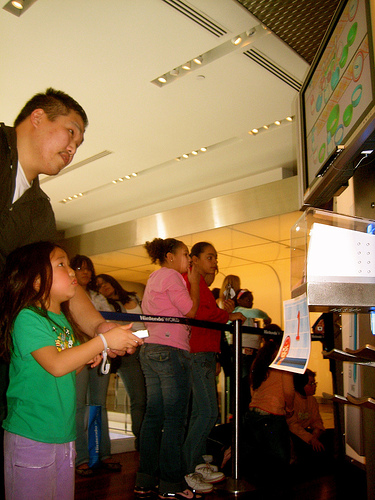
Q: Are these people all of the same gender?
A: Yes, all the people are female.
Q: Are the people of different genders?
A: No, all the people are female.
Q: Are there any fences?
A: No, there are no fences.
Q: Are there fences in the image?
A: No, there are no fences.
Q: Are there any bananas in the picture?
A: Yes, there is a banana.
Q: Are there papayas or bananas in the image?
A: Yes, there is a banana.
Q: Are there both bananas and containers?
A: No, there is a banana but no containers.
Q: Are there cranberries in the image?
A: No, there are no cranberries.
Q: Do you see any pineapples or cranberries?
A: No, there are no cranberries or pineapples.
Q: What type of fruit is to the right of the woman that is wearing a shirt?
A: The fruit is a banana.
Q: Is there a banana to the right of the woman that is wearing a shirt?
A: Yes, there is a banana to the right of the woman.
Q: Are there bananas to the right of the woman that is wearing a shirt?
A: Yes, there is a banana to the right of the woman.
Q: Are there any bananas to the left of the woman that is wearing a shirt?
A: No, the banana is to the right of the woman.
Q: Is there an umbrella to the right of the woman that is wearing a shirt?
A: No, there is a banana to the right of the woman.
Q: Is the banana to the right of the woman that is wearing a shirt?
A: Yes, the banana is to the right of the woman.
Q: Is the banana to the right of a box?
A: No, the banana is to the right of the woman.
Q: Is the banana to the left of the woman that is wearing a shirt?
A: No, the banana is to the right of the woman.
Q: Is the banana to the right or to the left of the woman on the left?
A: The banana is to the right of the woman.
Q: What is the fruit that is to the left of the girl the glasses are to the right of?
A: The fruit is a banana.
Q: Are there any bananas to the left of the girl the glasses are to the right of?
A: Yes, there is a banana to the left of the girl.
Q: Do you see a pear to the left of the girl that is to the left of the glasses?
A: No, there is a banana to the left of the girl.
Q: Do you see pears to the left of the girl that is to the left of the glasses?
A: No, there is a banana to the left of the girl.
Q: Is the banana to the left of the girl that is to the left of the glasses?
A: Yes, the banana is to the left of the girl.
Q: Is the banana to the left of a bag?
A: No, the banana is to the left of the girl.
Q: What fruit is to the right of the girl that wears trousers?
A: The fruit is a banana.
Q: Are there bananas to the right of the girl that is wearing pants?
A: Yes, there is a banana to the right of the girl.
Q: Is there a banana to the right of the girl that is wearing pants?
A: Yes, there is a banana to the right of the girl.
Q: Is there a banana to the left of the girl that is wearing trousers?
A: No, the banana is to the right of the girl.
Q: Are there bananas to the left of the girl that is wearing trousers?
A: No, the banana is to the right of the girl.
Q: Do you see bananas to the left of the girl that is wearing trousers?
A: No, the banana is to the right of the girl.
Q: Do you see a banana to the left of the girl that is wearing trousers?
A: No, the banana is to the right of the girl.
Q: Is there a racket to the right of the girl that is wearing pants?
A: No, there is a banana to the right of the girl.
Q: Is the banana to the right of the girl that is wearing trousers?
A: Yes, the banana is to the right of the girl.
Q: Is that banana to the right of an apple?
A: No, the banana is to the right of the girl.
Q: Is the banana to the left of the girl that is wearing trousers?
A: No, the banana is to the right of the girl.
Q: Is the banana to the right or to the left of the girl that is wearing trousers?
A: The banana is to the right of the girl.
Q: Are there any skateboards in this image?
A: No, there are no skateboards.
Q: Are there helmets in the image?
A: No, there are no helmets.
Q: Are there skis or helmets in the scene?
A: No, there are no helmets or skis.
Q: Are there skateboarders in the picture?
A: No, there are no skateboarders.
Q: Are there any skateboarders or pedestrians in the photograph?
A: No, there are no skateboarders or pedestrians.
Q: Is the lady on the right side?
A: Yes, the lady is on the right of the image.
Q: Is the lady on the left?
A: No, the lady is on the right of the image.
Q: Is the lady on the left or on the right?
A: The lady is on the right of the image.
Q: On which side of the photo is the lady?
A: The lady is on the right of the image.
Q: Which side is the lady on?
A: The lady is on the right of the image.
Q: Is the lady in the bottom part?
A: Yes, the lady is in the bottom of the image.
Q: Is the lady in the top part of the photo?
A: No, the lady is in the bottom of the image.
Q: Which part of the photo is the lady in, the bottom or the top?
A: The lady is in the bottom of the image.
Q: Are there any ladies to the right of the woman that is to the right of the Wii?
A: Yes, there is a lady to the right of the woman.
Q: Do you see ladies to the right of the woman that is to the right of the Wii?
A: Yes, there is a lady to the right of the woman.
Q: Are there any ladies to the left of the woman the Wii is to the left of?
A: No, the lady is to the right of the woman.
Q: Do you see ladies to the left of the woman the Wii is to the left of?
A: No, the lady is to the right of the woman.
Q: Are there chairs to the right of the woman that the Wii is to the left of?
A: No, there is a lady to the right of the woman.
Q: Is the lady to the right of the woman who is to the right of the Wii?
A: Yes, the lady is to the right of the woman.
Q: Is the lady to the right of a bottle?
A: No, the lady is to the right of the woman.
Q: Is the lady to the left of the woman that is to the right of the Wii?
A: No, the lady is to the right of the woman.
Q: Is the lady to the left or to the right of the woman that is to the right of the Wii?
A: The lady is to the right of the woman.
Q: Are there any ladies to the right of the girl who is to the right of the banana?
A: Yes, there is a lady to the right of the girl.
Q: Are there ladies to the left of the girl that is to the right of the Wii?
A: No, the lady is to the right of the girl.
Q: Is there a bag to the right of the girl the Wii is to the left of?
A: No, there is a lady to the right of the girl.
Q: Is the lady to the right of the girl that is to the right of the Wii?
A: Yes, the lady is to the right of the girl.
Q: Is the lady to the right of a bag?
A: No, the lady is to the right of the girl.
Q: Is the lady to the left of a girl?
A: No, the lady is to the right of a girl.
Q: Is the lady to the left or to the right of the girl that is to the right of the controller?
A: The lady is to the right of the girl.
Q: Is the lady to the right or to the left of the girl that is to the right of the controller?
A: The lady is to the right of the girl.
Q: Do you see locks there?
A: No, there are no locks.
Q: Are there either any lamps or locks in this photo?
A: No, there are no locks or lamps.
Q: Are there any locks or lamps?
A: No, there are no locks or lamps.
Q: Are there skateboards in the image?
A: No, there are no skateboards.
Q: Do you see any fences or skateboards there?
A: No, there are no skateboards or fences.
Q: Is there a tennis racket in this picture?
A: No, there are no rackets.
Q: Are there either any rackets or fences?
A: No, there are no rackets or fences.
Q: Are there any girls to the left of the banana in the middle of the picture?
A: Yes, there is a girl to the left of the banana.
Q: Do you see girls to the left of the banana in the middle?
A: Yes, there is a girl to the left of the banana.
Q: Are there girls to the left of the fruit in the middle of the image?
A: Yes, there is a girl to the left of the banana.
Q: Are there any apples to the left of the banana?
A: No, there is a girl to the left of the banana.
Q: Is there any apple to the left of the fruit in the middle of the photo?
A: No, there is a girl to the left of the banana.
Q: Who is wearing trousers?
A: The girl is wearing trousers.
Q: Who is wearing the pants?
A: The girl is wearing trousers.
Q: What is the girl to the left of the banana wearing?
A: The girl is wearing trousers.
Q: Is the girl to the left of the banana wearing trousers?
A: Yes, the girl is wearing trousers.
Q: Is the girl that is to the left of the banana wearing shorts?
A: No, the girl is wearing trousers.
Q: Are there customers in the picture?
A: No, there are no customers.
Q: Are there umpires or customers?
A: No, there are no customers or umpires.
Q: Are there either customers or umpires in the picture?
A: No, there are no customers or umpires.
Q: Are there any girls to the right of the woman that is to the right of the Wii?
A: Yes, there is a girl to the right of the woman.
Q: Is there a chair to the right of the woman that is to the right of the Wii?
A: No, there is a girl to the right of the woman.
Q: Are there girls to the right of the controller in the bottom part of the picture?
A: Yes, there is a girl to the right of the controller.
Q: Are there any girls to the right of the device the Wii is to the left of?
A: Yes, there is a girl to the right of the controller.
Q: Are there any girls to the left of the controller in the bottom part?
A: No, the girl is to the right of the controller.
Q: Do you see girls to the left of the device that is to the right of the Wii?
A: No, the girl is to the right of the controller.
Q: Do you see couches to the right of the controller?
A: No, there is a girl to the right of the controller.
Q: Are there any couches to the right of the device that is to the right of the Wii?
A: No, there is a girl to the right of the controller.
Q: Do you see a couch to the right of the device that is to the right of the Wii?
A: No, there is a girl to the right of the controller.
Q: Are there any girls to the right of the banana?
A: Yes, there is a girl to the right of the banana.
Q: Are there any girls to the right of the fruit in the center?
A: Yes, there is a girl to the right of the banana.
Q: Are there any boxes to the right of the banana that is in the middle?
A: No, there is a girl to the right of the banana.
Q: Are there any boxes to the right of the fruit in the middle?
A: No, there is a girl to the right of the banana.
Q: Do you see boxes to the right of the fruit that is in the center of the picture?
A: No, there is a girl to the right of the banana.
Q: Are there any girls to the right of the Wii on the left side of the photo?
A: Yes, there is a girl to the right of the Wii.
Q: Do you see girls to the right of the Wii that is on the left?
A: Yes, there is a girl to the right of the Wii.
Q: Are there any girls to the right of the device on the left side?
A: Yes, there is a girl to the right of the Wii.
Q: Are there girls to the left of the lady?
A: Yes, there is a girl to the left of the lady.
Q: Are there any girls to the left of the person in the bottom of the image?
A: Yes, there is a girl to the left of the lady.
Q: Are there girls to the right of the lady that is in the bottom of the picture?
A: No, the girl is to the left of the lady.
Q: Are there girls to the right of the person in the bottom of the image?
A: No, the girl is to the left of the lady.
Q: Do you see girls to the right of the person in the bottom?
A: No, the girl is to the left of the lady.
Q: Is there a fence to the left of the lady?
A: No, there is a girl to the left of the lady.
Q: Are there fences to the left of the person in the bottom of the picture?
A: No, there is a girl to the left of the lady.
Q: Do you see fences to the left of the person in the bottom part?
A: No, there is a girl to the left of the lady.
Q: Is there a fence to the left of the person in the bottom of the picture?
A: No, there is a girl to the left of the lady.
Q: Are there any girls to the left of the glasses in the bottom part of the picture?
A: Yes, there is a girl to the left of the glasses.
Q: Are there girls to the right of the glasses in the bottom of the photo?
A: No, the girl is to the left of the glasses.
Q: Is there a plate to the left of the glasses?
A: No, there is a girl to the left of the glasses.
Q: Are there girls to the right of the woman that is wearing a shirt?
A: Yes, there is a girl to the right of the woman.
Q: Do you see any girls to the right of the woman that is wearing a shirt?
A: Yes, there is a girl to the right of the woman.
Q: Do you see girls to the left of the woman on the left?
A: No, the girl is to the right of the woman.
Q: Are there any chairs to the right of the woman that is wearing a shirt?
A: No, there is a girl to the right of the woman.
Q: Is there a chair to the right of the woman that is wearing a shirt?
A: No, there is a girl to the right of the woman.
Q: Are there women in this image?
A: Yes, there is a woman.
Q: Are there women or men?
A: Yes, there is a woman.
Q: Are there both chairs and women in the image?
A: No, there is a woman but no chairs.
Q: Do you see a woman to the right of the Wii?
A: Yes, there is a woman to the right of the Wii.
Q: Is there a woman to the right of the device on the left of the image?
A: Yes, there is a woman to the right of the Wii.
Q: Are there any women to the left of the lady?
A: Yes, there is a woman to the left of the lady.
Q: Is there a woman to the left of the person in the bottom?
A: Yes, there is a woman to the left of the lady.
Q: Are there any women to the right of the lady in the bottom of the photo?
A: No, the woman is to the left of the lady.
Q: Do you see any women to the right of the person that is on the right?
A: No, the woman is to the left of the lady.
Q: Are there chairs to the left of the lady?
A: No, there is a woman to the left of the lady.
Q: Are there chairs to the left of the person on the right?
A: No, there is a woman to the left of the lady.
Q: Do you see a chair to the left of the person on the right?
A: No, there is a woman to the left of the lady.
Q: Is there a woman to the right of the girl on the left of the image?
A: Yes, there is a woman to the right of the girl.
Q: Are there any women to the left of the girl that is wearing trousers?
A: No, the woman is to the right of the girl.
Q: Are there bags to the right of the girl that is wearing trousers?
A: No, there is a woman to the right of the girl.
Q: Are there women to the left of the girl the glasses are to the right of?
A: Yes, there is a woman to the left of the girl.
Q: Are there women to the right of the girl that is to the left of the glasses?
A: No, the woman is to the left of the girl.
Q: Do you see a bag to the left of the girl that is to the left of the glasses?
A: No, there is a woman to the left of the girl.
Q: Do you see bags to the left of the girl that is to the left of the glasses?
A: No, there is a woman to the left of the girl.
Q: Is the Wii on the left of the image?
A: Yes, the Wii is on the left of the image.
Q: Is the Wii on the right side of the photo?
A: No, the Wii is on the left of the image.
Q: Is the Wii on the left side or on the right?
A: The Wii is on the left of the image.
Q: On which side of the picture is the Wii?
A: The Wii is on the left of the image.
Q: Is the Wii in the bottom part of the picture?
A: Yes, the Wii is in the bottom of the image.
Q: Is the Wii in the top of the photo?
A: No, the Wii is in the bottom of the image.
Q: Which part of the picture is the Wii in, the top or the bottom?
A: The Wii is in the bottom of the image.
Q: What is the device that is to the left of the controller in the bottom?
A: The device is a Wii.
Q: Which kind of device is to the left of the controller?
A: The device is a Wii.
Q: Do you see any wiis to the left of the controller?
A: Yes, there is a Wii to the left of the controller.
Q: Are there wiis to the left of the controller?
A: Yes, there is a Wii to the left of the controller.